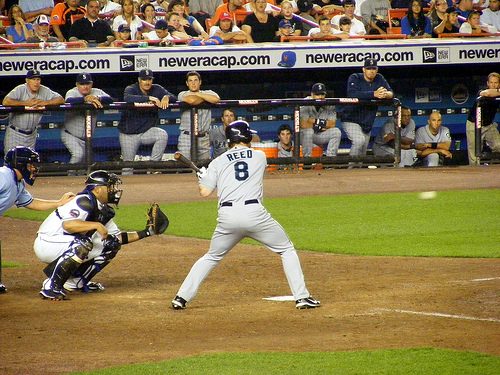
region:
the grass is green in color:
[377, 213, 408, 245]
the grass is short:
[360, 203, 424, 253]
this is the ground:
[215, 287, 250, 344]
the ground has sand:
[125, 317, 167, 347]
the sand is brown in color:
[105, 318, 148, 345]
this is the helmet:
[227, 126, 252, 133]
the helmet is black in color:
[234, 123, 251, 139]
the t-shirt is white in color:
[230, 186, 254, 203]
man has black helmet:
[219, 117, 244, 144]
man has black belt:
[217, 202, 262, 219]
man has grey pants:
[180, 212, 310, 304]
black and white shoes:
[287, 287, 332, 309]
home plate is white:
[263, 282, 301, 312]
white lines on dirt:
[346, 297, 488, 343]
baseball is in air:
[399, 149, 476, 230]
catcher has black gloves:
[140, 172, 168, 249]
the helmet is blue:
[218, 117, 258, 143]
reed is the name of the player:
[224, 147, 258, 163]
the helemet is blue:
[13, 143, 43, 176]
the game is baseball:
[3, 3, 498, 374]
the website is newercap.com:
[298, 42, 413, 67]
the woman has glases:
[405, 1, 430, 37]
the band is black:
[431, 137, 437, 152]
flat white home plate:
[258, 289, 303, 304]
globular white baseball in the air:
[416, 185, 440, 205]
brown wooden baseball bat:
[171, 148, 208, 178]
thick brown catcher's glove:
[142, 200, 172, 239]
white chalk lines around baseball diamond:
[281, 270, 498, 331]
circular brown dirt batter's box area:
[0, 212, 462, 369]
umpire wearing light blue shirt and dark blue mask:
[0, 141, 80, 306]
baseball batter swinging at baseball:
[166, 117, 323, 314]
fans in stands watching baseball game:
[0, 0, 498, 51]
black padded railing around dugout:
[1, 93, 498, 171]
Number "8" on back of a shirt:
[225, 155, 255, 187]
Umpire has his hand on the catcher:
[0, 136, 171, 303]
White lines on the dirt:
[370, 265, 496, 327]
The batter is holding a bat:
[161, 111, 326, 316]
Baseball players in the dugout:
[0, 65, 496, 171]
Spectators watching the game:
[0, 0, 496, 51]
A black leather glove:
[136, 195, 176, 241]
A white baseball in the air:
[410, 180, 441, 205]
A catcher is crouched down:
[27, 161, 172, 307]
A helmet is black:
[215, 112, 258, 152]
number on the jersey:
[231, 158, 254, 186]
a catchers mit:
[143, 200, 174, 240]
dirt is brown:
[341, 259, 386, 290]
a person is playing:
[170, 116, 321, 316]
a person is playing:
[43, 168, 170, 301]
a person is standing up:
[6, 69, 58, 154]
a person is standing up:
[65, 78, 110, 164]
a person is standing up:
[112, 69, 174, 172]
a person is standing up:
[172, 66, 215, 160]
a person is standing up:
[333, 52, 390, 167]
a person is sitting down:
[414, 109, 446, 169]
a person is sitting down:
[274, 125, 301, 160]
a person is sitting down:
[404, 4, 434, 36]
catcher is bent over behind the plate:
[33, 164, 171, 301]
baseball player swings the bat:
[169, 118, 321, 313]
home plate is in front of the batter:
[258, 288, 305, 301]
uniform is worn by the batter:
[177, 148, 310, 305]